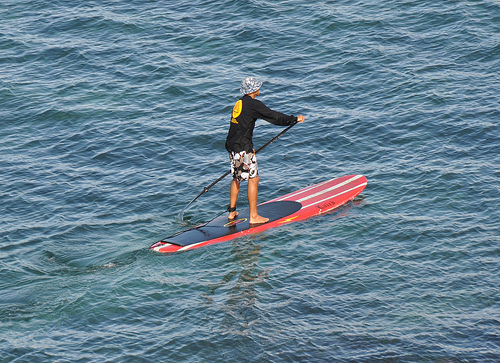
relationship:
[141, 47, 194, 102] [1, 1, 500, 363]
waves in water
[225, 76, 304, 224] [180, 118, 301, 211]
man holding paddle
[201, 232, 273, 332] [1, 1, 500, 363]
reflection in water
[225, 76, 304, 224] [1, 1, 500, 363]
man in water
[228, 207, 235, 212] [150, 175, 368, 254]
strap connected to board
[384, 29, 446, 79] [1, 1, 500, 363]
portion of water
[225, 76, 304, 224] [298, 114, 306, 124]
man has right hand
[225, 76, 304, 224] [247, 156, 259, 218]
man has right leg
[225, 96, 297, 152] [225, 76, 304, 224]
shirt worn by man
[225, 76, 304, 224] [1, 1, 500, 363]
man on water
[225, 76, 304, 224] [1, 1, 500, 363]
man paddle boarding on water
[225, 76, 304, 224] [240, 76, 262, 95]
man wearing hat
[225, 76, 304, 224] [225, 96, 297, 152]
man wearing shirt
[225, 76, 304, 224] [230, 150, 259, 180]
man wearing shorts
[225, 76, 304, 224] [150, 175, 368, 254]
man standing on board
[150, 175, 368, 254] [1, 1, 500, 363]
board in water